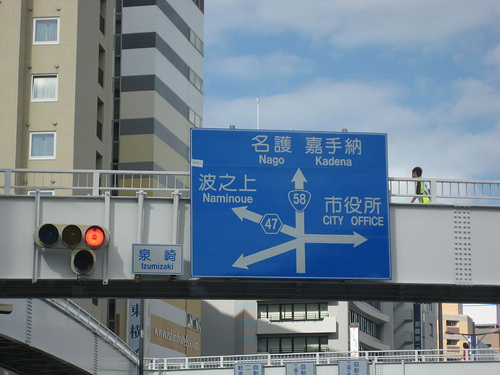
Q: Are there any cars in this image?
A: No, there are no cars.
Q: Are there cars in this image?
A: No, there are no cars.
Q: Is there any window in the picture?
A: Yes, there is a window.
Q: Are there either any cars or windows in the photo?
A: Yes, there is a window.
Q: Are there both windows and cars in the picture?
A: No, there is a window but no cars.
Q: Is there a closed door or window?
A: Yes, there is a closed window.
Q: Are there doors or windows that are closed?
A: Yes, the window is closed.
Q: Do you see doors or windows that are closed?
A: Yes, the window is closed.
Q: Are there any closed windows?
A: Yes, there is a closed window.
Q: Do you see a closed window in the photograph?
A: Yes, there is a closed window.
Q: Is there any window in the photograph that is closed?
A: Yes, there is a window that is closed.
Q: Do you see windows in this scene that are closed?
A: Yes, there is a window that is closed.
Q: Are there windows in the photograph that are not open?
A: Yes, there is an closed window.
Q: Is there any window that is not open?
A: Yes, there is an closed window.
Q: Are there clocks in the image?
A: No, there are no clocks.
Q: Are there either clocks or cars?
A: No, there are no clocks or cars.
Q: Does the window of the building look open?
A: No, the window is closed.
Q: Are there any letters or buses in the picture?
A: Yes, there are letters.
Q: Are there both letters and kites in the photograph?
A: No, there are letters but no kites.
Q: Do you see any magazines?
A: No, there are no magazines.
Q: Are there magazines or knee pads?
A: No, there are no magazines or knee pads.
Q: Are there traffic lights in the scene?
A: Yes, there is a traffic light.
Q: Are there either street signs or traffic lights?
A: Yes, there is a traffic light.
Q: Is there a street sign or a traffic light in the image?
A: Yes, there is a traffic light.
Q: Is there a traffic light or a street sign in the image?
A: Yes, there is a traffic light.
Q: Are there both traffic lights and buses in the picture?
A: No, there is a traffic light but no buses.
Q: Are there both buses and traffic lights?
A: No, there is a traffic light but no buses.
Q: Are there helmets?
A: No, there are no helmets.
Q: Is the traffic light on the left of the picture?
A: Yes, the traffic light is on the left of the image.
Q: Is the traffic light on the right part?
A: No, the traffic light is on the left of the image.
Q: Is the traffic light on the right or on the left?
A: The traffic light is on the left of the image.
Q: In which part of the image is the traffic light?
A: The traffic light is on the left of the image.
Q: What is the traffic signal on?
A: The traffic signal is on the bridge.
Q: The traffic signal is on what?
A: The traffic signal is on the bridge.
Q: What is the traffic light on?
A: The traffic signal is on the bridge.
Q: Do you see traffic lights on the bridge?
A: Yes, there is a traffic light on the bridge.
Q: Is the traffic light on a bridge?
A: Yes, the traffic light is on a bridge.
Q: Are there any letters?
A: Yes, there are letters.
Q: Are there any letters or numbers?
A: Yes, there are letters.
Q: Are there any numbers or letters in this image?
A: Yes, there are letters.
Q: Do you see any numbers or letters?
A: Yes, there are letters.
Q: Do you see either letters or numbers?
A: Yes, there are letters.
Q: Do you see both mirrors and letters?
A: No, there are letters but no mirrors.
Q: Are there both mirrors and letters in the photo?
A: No, there are letters but no mirrors.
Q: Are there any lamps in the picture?
A: No, there are no lamps.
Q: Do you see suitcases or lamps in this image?
A: No, there are no lamps or suitcases.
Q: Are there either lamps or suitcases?
A: No, there are no lamps or suitcases.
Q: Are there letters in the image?
A: Yes, there are letters.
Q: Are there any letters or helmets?
A: Yes, there are letters.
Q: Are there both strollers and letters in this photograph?
A: No, there are letters but no strollers.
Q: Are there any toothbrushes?
A: No, there are no toothbrushes.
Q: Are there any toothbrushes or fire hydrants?
A: No, there are no toothbrushes or fire hydrants.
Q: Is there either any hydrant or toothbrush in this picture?
A: No, there are no toothbrushes or fire hydrants.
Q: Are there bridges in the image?
A: Yes, there is a bridge.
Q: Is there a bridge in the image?
A: Yes, there is a bridge.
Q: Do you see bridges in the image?
A: Yes, there is a bridge.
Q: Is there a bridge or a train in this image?
A: Yes, there is a bridge.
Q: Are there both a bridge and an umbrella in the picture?
A: No, there is a bridge but no umbrellas.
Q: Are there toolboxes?
A: No, there are no toolboxes.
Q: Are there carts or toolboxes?
A: No, there are no toolboxes or carts.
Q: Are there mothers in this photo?
A: No, there are no mothers.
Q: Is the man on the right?
A: Yes, the man is on the right of the image.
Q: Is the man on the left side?
A: No, the man is on the right of the image.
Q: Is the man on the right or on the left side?
A: The man is on the right of the image.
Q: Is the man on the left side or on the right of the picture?
A: The man is on the right of the image.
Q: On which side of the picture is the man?
A: The man is on the right of the image.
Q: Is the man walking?
A: Yes, the man is walking.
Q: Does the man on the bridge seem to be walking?
A: Yes, the man is walking.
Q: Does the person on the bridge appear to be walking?
A: Yes, the man is walking.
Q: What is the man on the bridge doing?
A: The man is walking.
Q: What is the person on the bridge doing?
A: The man is walking.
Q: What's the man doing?
A: The man is walking.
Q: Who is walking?
A: The man is walking.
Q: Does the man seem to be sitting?
A: No, the man is walking.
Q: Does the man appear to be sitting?
A: No, the man is walking.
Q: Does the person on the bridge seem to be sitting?
A: No, the man is walking.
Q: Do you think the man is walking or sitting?
A: The man is walking.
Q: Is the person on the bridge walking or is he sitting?
A: The man is walking.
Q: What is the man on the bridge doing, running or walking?
A: The man is walking.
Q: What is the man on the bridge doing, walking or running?
A: The man is walking.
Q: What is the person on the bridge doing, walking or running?
A: The man is walking.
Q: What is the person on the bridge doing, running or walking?
A: The man is walking.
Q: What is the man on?
A: The man is on the bridge.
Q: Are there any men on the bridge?
A: Yes, there is a man on the bridge.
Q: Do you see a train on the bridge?
A: No, there is a man on the bridge.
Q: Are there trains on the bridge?
A: No, there is a man on the bridge.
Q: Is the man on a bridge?
A: Yes, the man is on a bridge.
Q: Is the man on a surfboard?
A: No, the man is on a bridge.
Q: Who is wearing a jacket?
A: The man is wearing a jacket.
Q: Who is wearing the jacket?
A: The man is wearing a jacket.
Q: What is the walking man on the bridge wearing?
A: The man is wearing a jacket.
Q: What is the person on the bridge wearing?
A: The man is wearing a jacket.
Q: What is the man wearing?
A: The man is wearing a jacket.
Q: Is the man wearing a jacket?
A: Yes, the man is wearing a jacket.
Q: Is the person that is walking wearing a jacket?
A: Yes, the man is wearing a jacket.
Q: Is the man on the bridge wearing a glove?
A: No, the man is wearing a jacket.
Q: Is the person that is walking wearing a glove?
A: No, the man is wearing a jacket.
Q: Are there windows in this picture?
A: Yes, there is a window.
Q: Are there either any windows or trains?
A: Yes, there is a window.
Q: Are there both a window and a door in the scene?
A: No, there is a window but no doors.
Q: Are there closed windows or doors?
A: Yes, there is a closed window.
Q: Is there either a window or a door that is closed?
A: Yes, the window is closed.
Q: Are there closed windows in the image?
A: Yes, there is a closed window.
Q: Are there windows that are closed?
A: Yes, there is a window that is closed.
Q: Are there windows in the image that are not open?
A: Yes, there is an closed window.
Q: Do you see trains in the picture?
A: No, there are no trains.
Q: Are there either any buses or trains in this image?
A: No, there are no trains or buses.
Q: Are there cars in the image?
A: No, there are no cars.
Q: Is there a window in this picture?
A: Yes, there is a window.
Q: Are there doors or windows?
A: Yes, there is a window.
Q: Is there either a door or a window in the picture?
A: Yes, there is a window.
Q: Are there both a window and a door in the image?
A: No, there is a window but no doors.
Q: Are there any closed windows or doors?
A: Yes, there is a closed window.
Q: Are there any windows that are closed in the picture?
A: Yes, there is a closed window.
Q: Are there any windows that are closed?
A: Yes, there is a window that is closed.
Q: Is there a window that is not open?
A: Yes, there is an closed window.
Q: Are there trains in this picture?
A: No, there are no trains.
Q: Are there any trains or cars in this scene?
A: No, there are no trains or cars.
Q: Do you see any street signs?
A: Yes, there is a street sign.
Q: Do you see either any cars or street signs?
A: Yes, there is a street sign.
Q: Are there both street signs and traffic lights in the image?
A: Yes, there are both a street sign and a traffic light.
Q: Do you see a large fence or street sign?
A: Yes, there is a large street sign.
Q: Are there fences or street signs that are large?
A: Yes, the street sign is large.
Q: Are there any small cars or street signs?
A: Yes, there is a small street sign.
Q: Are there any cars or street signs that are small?
A: Yes, the street sign is small.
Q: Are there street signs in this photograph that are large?
A: Yes, there is a large street sign.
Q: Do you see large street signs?
A: Yes, there is a large street sign.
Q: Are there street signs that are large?
A: Yes, there is a street sign that is large.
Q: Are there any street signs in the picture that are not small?
A: Yes, there is a large street sign.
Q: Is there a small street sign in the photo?
A: Yes, there is a small street sign.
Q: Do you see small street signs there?
A: Yes, there is a small street sign.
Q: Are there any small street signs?
A: Yes, there is a small street sign.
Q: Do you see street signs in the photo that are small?
A: Yes, there is a street sign that is small.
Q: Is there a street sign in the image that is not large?
A: Yes, there is a small street sign.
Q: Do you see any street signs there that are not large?
A: Yes, there is a small street sign.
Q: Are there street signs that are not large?
A: Yes, there is a small street sign.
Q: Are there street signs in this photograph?
A: Yes, there is a street sign.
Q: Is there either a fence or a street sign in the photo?
A: Yes, there is a street sign.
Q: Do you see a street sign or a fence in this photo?
A: Yes, there is a street sign.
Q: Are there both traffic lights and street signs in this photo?
A: Yes, there are both a street sign and a traffic light.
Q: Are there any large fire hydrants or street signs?
A: Yes, there is a large street sign.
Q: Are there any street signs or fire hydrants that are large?
A: Yes, the street sign is large.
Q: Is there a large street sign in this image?
A: Yes, there is a large street sign.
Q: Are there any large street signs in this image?
A: Yes, there is a large street sign.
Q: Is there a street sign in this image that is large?
A: Yes, there is a street sign that is large.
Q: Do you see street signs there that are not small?
A: Yes, there is a large street sign.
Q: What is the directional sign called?
A: The sign is a street sign.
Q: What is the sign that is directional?
A: The sign is a street sign.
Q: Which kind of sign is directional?
A: The sign is a street sign.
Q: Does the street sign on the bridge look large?
A: Yes, the street sign is large.